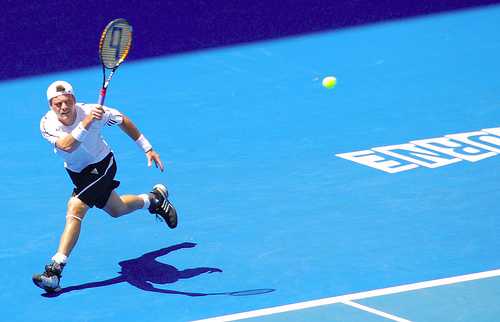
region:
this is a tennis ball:
[313, 63, 340, 98]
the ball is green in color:
[318, 72, 342, 92]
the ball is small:
[308, 68, 340, 97]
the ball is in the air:
[311, 66, 341, 91]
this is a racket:
[78, 12, 139, 114]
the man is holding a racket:
[73, 13, 153, 134]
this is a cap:
[40, 79, 79, 99]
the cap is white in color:
[48, 85, 63, 95]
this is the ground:
[217, 155, 300, 220]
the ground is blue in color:
[233, 184, 290, 256]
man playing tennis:
[23, 8, 204, 292]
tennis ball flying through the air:
[316, 52, 351, 115]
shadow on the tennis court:
[100, 239, 278, 304]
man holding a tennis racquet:
[35, 14, 140, 158]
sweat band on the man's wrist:
[130, 125, 154, 160]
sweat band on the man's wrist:
[71, 120, 98, 152]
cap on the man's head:
[39, 72, 76, 115]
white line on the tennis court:
[356, 278, 456, 310]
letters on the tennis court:
[342, 113, 459, 200]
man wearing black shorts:
[30, 66, 165, 299]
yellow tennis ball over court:
[211, 6, 496, 257]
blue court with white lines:
[184, 7, 497, 320]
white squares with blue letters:
[335, 125, 498, 175]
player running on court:
[32, 15, 177, 293]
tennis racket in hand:
[90, 16, 135, 122]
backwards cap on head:
[47, 79, 75, 124]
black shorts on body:
[31, 152, 180, 291]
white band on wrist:
[133, 132, 164, 170]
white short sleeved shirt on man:
[40, 80, 122, 170]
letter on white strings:
[102, 20, 131, 65]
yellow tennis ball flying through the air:
[319, 73, 337, 90]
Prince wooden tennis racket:
[98, 16, 133, 106]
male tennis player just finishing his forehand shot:
[29, 18, 184, 294]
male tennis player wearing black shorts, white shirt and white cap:
[30, 71, 181, 293]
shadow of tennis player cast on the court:
[41, 237, 275, 302]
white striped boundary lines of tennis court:
[171, 264, 498, 320]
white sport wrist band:
[133, 131, 155, 152]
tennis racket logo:
[107, 23, 122, 60]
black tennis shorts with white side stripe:
[65, 150, 121, 202]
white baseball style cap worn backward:
[46, 78, 73, 96]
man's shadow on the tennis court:
[41, 240, 278, 297]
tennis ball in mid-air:
[322, 74, 339, 89]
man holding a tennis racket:
[31, 18, 179, 293]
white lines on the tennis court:
[186, 267, 498, 320]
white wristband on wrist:
[133, 133, 155, 155]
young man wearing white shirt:
[31, 80, 179, 296]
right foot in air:
[148, 179, 178, 231]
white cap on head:
[45, 76, 76, 120]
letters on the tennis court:
[333, 125, 498, 176]